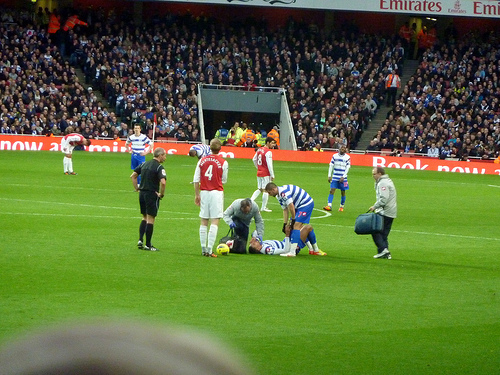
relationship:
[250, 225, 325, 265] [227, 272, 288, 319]
player lying down on floor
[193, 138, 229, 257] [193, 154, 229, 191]
member wearing a jersey number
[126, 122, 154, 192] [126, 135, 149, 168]
player wearing a uniform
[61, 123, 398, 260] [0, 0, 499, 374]
players in a arena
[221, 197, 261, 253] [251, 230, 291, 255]
doctor examining player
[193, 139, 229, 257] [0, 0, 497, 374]
soccer player in arena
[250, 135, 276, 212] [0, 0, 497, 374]
team member in arena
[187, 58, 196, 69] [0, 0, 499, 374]
spectator watching from arena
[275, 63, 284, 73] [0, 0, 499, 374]
spectator watching from arena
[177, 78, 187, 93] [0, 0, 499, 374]
spectator watching from arena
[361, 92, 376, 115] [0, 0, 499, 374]
spectator watching from arena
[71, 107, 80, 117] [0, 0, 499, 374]
spectator watching from arena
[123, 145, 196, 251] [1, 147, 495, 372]
player on field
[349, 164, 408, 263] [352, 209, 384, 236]
doctor holding bag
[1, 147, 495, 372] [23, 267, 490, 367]
field has grass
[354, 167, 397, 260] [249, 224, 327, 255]
doctor approaching player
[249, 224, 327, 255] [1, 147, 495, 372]
player laying in field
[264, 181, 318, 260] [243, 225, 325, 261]
player looking at player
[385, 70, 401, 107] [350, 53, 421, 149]
man walking down stairs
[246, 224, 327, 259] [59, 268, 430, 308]
player laying on ground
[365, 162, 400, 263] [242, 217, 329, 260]
man walking toward player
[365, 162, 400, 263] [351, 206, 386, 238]
man has bag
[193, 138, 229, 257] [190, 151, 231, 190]
member wearing jersey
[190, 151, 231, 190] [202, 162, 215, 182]
jersey has number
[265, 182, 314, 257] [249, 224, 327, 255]
player bending over player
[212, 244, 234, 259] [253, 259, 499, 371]
soccer ball on ground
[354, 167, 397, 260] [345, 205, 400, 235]
doctor holding bag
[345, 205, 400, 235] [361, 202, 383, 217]
bag in hand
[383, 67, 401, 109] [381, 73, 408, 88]
man wearing vest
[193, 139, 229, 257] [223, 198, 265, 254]
soccer player assisting doctor